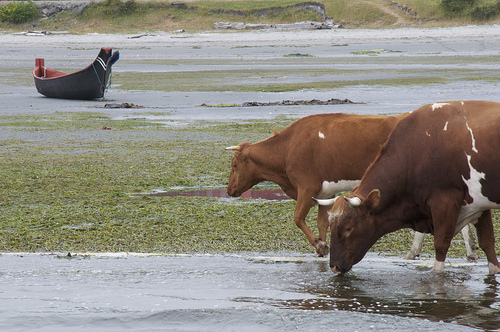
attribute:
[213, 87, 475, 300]
cows — pictured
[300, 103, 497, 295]
cow — brown, white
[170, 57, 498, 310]
cow —  dark brown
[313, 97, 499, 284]
cow — brown and white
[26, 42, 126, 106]
boat — black, red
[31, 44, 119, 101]
boat — red, black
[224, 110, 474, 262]
cow —  dark brown